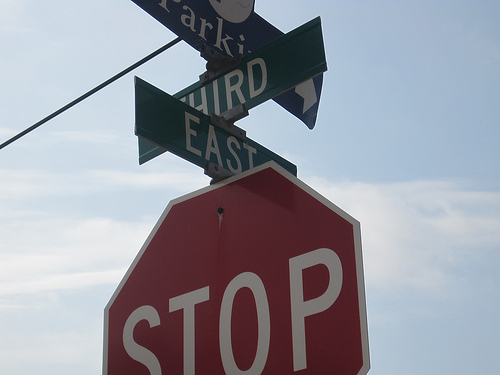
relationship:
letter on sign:
[115, 294, 164, 372] [135, 14, 328, 165]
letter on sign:
[162, 276, 214, 372] [135, 14, 328, 165]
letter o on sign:
[213, 265, 274, 372] [135, 14, 328, 165]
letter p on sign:
[281, 236, 346, 372] [135, 14, 328, 165]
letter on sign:
[182, 105, 203, 154] [119, 69, 302, 181]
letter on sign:
[202, 122, 223, 167] [119, 69, 302, 181]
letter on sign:
[222, 129, 245, 176] [119, 69, 302, 181]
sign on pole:
[132, 74, 297, 179] [210, 9, 242, 178]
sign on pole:
[126, 7, 333, 170] [206, 7, 238, 181]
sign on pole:
[135, 5, 324, 132] [208, 4, 240, 178]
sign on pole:
[135, 14, 328, 165] [201, 4, 241, 184]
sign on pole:
[132, 74, 297, 179] [201, 4, 241, 184]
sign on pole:
[126, 7, 333, 170] [202, 0, 243, 190]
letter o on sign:
[213, 270, 274, 375] [135, 14, 328, 165]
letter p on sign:
[287, 246, 344, 372] [135, 14, 328, 165]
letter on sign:
[182, 109, 206, 158] [132, 74, 297, 179]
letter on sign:
[222, 136, 245, 175] [132, 74, 297, 179]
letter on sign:
[239, 138, 260, 170] [132, 74, 297, 179]